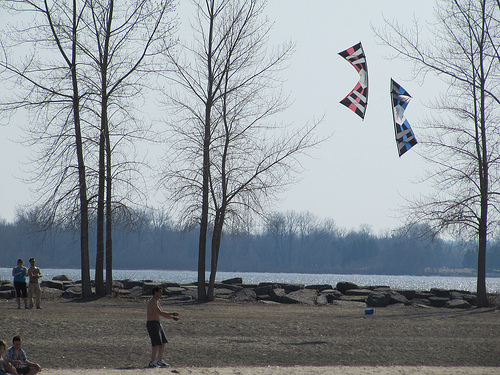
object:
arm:
[153, 303, 171, 319]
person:
[13, 258, 33, 309]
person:
[25, 257, 44, 309]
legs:
[147, 326, 163, 361]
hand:
[172, 310, 179, 316]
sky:
[0, 0, 499, 239]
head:
[150, 286, 163, 296]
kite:
[390, 77, 417, 158]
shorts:
[145, 320, 168, 346]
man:
[144, 285, 182, 368]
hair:
[152, 285, 166, 292]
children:
[6, 334, 44, 374]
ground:
[0, 301, 498, 374]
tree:
[0, 0, 180, 297]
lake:
[0, 266, 499, 295]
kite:
[337, 40, 370, 121]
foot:
[145, 362, 158, 369]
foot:
[156, 358, 171, 368]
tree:
[157, 0, 333, 301]